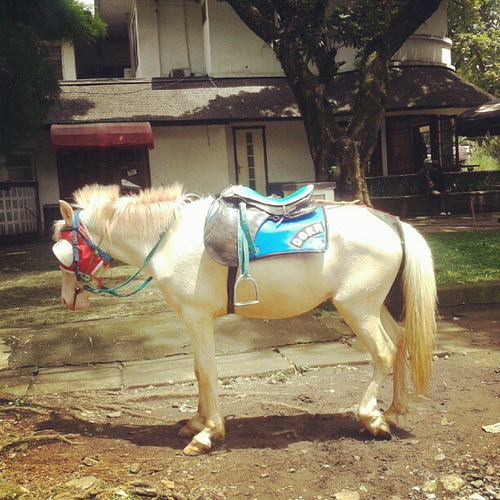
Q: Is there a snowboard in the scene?
A: No, there are no snowboards.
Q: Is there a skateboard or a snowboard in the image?
A: No, there are no snowboards or skateboards.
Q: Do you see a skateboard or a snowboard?
A: No, there are no snowboards or skateboards.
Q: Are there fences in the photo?
A: No, there are no fences.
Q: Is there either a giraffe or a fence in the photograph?
A: No, there are no fences or giraffes.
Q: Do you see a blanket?
A: Yes, there is a blanket.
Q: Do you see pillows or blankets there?
A: Yes, there is a blanket.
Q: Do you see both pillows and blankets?
A: No, there is a blanket but no pillows.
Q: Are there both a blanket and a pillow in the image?
A: No, there is a blanket but no pillows.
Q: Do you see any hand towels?
A: No, there are no hand towels.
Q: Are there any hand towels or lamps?
A: No, there are no hand towels or lamps.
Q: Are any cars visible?
A: No, there are no cars.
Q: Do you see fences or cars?
A: No, there are no cars or fences.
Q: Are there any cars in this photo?
A: No, there are no cars.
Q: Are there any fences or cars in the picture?
A: No, there are no cars or fences.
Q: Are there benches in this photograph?
A: Yes, there is a bench.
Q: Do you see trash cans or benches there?
A: Yes, there is a bench.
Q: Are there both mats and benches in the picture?
A: No, there is a bench but no mats.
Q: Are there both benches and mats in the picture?
A: No, there is a bench but no mats.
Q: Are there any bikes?
A: No, there are no bikes.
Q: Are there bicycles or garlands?
A: No, there are no bicycles or garlands.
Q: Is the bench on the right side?
A: Yes, the bench is on the right of the image.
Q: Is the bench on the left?
A: No, the bench is on the right of the image.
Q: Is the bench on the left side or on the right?
A: The bench is on the right of the image.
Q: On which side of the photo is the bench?
A: The bench is on the right of the image.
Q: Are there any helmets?
A: No, there are no helmets.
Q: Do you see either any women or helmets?
A: No, there are no helmets or women.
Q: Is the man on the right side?
A: Yes, the man is on the right of the image.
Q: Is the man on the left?
A: No, the man is on the right of the image.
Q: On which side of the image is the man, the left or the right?
A: The man is on the right of the image.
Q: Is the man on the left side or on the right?
A: The man is on the right of the image.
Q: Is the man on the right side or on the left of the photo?
A: The man is on the right of the image.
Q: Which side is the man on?
A: The man is on the right of the image.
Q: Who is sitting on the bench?
A: The man is sitting on the bench.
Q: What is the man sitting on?
A: The man is sitting on the bench.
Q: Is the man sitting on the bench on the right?
A: Yes, the man is sitting on the bench.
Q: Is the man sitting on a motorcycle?
A: No, the man is sitting on the bench.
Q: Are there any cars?
A: No, there are no cars.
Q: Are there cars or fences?
A: No, there are no cars or fences.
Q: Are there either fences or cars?
A: No, there are no cars or fences.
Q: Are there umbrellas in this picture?
A: No, there are no umbrellas.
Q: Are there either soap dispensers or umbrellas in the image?
A: No, there are no umbrellas or soap dispensers.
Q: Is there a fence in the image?
A: No, there are no fences.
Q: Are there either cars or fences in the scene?
A: No, there are no fences or cars.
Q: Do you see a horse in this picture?
A: Yes, there is a horse.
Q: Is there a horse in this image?
A: Yes, there is a horse.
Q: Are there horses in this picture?
A: Yes, there is a horse.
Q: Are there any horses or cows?
A: Yes, there is a horse.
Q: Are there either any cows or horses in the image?
A: Yes, there is a horse.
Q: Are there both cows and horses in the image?
A: No, there is a horse but no cows.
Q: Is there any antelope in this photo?
A: No, there are no antelopes.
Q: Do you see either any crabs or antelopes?
A: No, there are no antelopes or crabs.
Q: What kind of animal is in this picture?
A: The animal is a horse.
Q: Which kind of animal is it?
A: The animal is a horse.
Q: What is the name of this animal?
A: This is a horse.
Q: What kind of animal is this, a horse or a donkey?
A: This is a horse.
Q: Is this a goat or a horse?
A: This is a horse.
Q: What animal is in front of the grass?
A: The horse is in front of the grass.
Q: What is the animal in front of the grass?
A: The animal is a horse.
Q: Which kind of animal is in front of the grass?
A: The animal is a horse.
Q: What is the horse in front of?
A: The horse is in front of the grass.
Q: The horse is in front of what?
A: The horse is in front of the grass.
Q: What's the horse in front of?
A: The horse is in front of the grass.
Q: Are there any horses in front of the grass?
A: Yes, there is a horse in front of the grass.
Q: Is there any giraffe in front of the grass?
A: No, there is a horse in front of the grass.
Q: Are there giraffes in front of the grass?
A: No, there is a horse in front of the grass.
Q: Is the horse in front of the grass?
A: Yes, the horse is in front of the grass.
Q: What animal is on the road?
A: The horse is on the road.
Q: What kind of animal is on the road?
A: The animal is a horse.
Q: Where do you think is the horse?
A: The horse is on the road.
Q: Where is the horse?
A: The horse is on the road.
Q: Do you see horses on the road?
A: Yes, there is a horse on the road.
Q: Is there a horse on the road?
A: Yes, there is a horse on the road.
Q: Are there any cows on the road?
A: No, there is a horse on the road.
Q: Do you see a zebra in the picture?
A: No, there are no zebras.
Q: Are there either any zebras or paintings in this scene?
A: No, there are no zebras or paintings.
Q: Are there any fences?
A: No, there are no fences.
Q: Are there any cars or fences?
A: No, there are no fences or cars.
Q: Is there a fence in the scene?
A: No, there are no fences.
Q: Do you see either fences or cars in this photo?
A: No, there are no fences or cars.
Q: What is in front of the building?
A: The tree is in front of the building.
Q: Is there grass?
A: Yes, there is grass.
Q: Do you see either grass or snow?
A: Yes, there is grass.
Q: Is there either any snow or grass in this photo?
A: Yes, there is grass.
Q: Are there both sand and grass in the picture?
A: No, there is grass but no sand.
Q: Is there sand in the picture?
A: No, there is no sand.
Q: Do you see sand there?
A: No, there is no sand.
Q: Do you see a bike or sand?
A: No, there are no sand or bikes.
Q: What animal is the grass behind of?
A: The grass is behind the horse.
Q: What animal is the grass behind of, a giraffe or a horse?
A: The grass is behind a horse.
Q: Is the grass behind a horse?
A: Yes, the grass is behind a horse.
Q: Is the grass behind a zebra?
A: No, the grass is behind a horse.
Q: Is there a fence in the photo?
A: No, there are no fences.